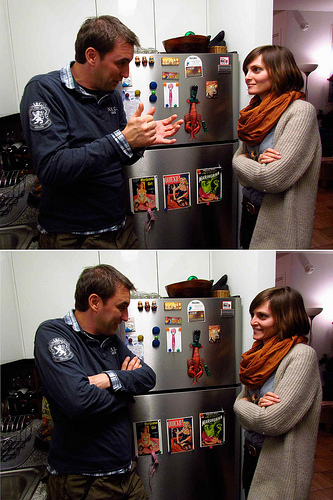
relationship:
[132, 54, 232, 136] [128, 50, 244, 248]
magnets on fridge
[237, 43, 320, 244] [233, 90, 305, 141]
woman wears scarf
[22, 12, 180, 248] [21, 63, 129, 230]
man wears shirt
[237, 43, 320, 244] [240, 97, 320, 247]
woman wears cardigan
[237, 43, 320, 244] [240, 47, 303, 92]
woman has hair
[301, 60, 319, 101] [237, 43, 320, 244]
light behind woman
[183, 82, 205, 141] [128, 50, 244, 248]
lobster on fridge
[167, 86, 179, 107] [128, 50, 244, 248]
picture on fridge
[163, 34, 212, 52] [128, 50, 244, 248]
basket on fridge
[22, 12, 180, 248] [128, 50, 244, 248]
man next to fridge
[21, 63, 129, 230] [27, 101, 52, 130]
shirt has patch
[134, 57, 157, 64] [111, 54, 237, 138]
magnets on door